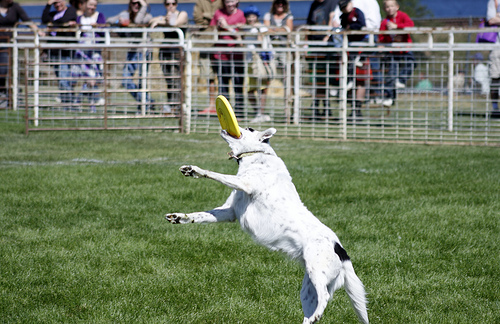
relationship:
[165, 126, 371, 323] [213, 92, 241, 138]
dog has frisbee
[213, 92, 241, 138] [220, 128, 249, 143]
frisbee in mouth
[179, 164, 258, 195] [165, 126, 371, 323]
leg of dog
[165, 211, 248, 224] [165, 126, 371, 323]
front right leg of dog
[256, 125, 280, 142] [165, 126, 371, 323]
left ear of dog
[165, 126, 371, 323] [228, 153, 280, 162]
dog has a collar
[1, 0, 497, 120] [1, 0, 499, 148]
spectators in distance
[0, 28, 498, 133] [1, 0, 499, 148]
fence in distance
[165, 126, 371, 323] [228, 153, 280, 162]
dog wearing collar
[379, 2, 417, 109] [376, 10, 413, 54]
child wearing shirt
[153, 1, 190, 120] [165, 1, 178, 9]
woman wearing sunglasses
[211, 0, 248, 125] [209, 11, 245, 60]
woman wearing shirt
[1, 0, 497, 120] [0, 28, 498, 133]
spectators behind fence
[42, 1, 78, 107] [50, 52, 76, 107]
person wearing jeans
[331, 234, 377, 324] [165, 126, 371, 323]
tail on dog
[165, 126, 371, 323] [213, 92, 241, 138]
dog catching frisbee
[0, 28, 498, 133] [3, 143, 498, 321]
fence around grass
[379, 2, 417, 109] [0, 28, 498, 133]
child standing on fence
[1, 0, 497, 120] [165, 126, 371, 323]
spectators watching dog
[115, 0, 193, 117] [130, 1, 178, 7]
women wearing sunglasses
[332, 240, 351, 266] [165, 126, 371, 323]
spot on dog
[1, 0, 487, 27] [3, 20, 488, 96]
roof on building